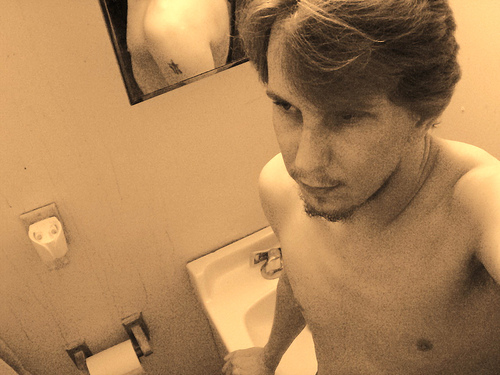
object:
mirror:
[92, 0, 253, 106]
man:
[217, 0, 500, 375]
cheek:
[342, 125, 406, 204]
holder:
[59, 309, 157, 375]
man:
[122, 0, 233, 95]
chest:
[276, 207, 500, 374]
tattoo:
[166, 58, 183, 76]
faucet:
[249, 243, 288, 283]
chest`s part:
[328, 263, 363, 297]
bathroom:
[0, 0, 500, 373]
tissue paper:
[25, 213, 74, 267]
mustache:
[288, 167, 341, 186]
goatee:
[301, 201, 365, 225]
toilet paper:
[84, 337, 148, 375]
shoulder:
[449, 136, 500, 185]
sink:
[185, 224, 321, 375]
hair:
[238, 0, 467, 132]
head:
[234, 0, 466, 227]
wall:
[0, 0, 500, 375]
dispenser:
[26, 214, 71, 265]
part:
[353, 169, 372, 183]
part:
[335, 283, 347, 294]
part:
[389, 288, 399, 299]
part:
[476, 151, 489, 163]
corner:
[110, 77, 187, 117]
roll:
[82, 335, 147, 375]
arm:
[255, 156, 309, 371]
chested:
[279, 202, 477, 375]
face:
[264, 43, 401, 222]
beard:
[288, 162, 400, 223]